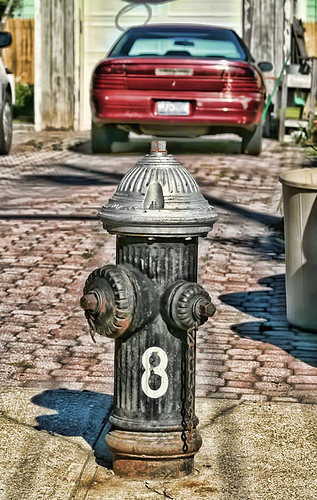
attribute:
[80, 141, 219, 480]
hydrant — gray, rusty, silver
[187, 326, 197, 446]
chain — rusty, hanging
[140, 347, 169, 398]
8 — white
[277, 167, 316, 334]
trash can — tan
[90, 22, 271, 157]
car — parked, red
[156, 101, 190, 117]
license plate — white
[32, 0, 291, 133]
garage — old, small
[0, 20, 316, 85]
fence — brown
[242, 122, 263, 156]
wheel — black